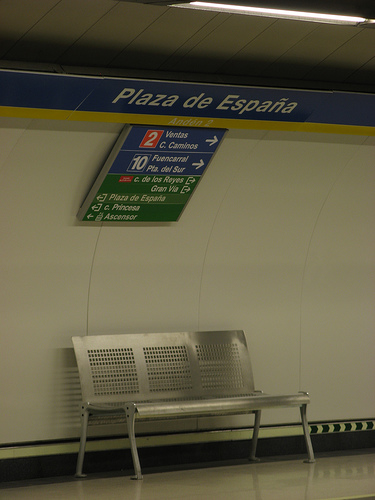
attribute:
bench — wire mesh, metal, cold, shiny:
[71, 328, 319, 481]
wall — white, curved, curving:
[0, 68, 372, 482]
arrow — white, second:
[190, 159, 207, 172]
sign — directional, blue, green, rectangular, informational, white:
[76, 122, 230, 225]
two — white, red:
[144, 131, 157, 147]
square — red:
[138, 129, 166, 148]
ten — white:
[132, 155, 148, 171]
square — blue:
[127, 151, 154, 174]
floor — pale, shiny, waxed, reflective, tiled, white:
[0, 447, 373, 500]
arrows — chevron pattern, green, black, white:
[308, 420, 373, 434]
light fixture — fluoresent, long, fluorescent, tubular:
[170, 0, 372, 27]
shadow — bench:
[52, 346, 140, 423]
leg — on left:
[123, 403, 143, 479]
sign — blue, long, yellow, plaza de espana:
[1, 69, 374, 136]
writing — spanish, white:
[111, 87, 298, 116]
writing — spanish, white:
[159, 130, 202, 151]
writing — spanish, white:
[144, 153, 189, 174]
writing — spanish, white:
[133, 174, 186, 193]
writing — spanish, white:
[107, 193, 168, 205]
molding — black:
[1, 419, 374, 483]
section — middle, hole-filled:
[142, 345, 198, 394]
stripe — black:
[0, 429, 374, 483]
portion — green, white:
[81, 175, 200, 224]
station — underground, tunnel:
[0, 0, 372, 499]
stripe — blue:
[0, 70, 374, 126]